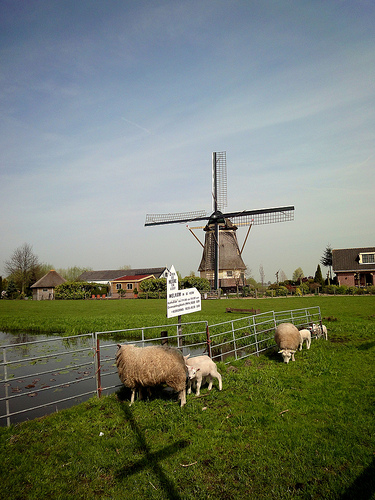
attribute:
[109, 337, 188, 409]
sheep — adult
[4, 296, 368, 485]
grass — green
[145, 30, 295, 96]
sky — blue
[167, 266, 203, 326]
board — white, instruction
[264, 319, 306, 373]
sheep — adult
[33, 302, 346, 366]
grass — green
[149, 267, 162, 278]
lamp — white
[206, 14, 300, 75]
sky — blue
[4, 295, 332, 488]
field — green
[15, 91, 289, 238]
clouds — white